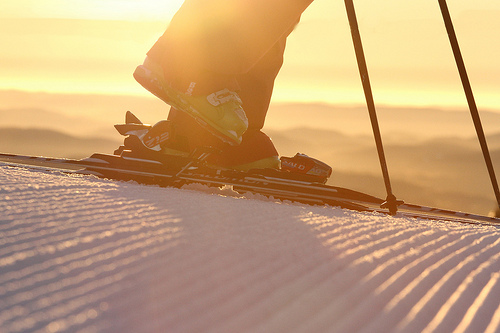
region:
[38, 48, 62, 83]
white clouds in blue sky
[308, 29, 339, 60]
white clouds in blue sky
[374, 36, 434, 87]
white clouds in blue sky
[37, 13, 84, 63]
white clouds in blue sky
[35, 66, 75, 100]
white clouds in blue sky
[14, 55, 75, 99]
white clouds in blue sky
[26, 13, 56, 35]
white clouds in blue sky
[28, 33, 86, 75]
white clouds in blue sky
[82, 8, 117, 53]
white clouds in blue sky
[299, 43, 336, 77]
white clouds in blue sky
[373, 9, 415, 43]
white clouds in blue sky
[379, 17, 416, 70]
white clouds in blue sky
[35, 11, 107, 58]
white clouds in blue sky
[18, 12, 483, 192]
this is a persons feet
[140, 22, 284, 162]
this is a right root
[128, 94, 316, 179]
this is a left foot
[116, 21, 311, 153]
right foot is lifted up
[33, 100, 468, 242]
person standing on skis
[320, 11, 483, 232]
a set of ski poles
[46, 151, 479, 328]
this is white snow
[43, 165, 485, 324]
tread marks in the snow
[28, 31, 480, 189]
a bright sunny day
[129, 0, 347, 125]
person wearing dark colored pants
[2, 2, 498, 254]
a person skiing at sunrise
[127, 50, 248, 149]
a foot in a green ski boot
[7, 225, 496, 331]
ripples of snow reflecting sunlight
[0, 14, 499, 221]
a skier heading downhill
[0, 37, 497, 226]
a foot coming off of a ski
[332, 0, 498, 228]
two ski poles against the snow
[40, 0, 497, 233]
a skier atop a mountain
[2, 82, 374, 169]
haze on distant hills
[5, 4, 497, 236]
a skier waiting for her turn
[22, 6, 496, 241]
a skier prepares to descent the mountain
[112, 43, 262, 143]
this is someone's right foot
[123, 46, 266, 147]
this is a ski boot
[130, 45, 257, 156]
the boot is green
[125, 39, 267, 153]
a green ski boot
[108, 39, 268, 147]
the boot is not mounted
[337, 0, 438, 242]
a black ski pole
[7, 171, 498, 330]
the snow has been raked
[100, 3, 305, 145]
the glare from the sunlight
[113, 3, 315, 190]
this person is getting into the ski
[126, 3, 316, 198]
the person is preparing to put their boot into the ski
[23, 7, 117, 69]
Sunset in the distance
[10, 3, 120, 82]
Sunset in the distance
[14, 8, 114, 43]
Sunset in the distance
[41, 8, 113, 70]
Sunset in the distance